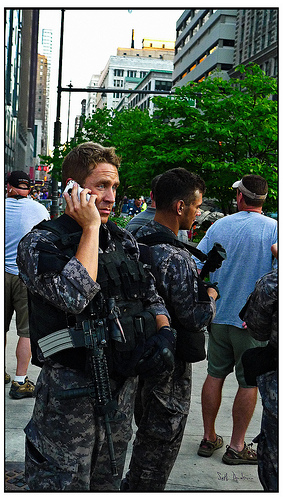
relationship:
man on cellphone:
[33, 140, 160, 493] [61, 180, 94, 210]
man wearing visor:
[188, 169, 279, 465] [218, 176, 267, 203]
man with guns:
[15, 140, 160, 493] [36, 254, 127, 471]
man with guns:
[15, 140, 160, 493] [189, 238, 231, 301]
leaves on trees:
[70, 66, 274, 201] [56, 83, 272, 221]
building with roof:
[122, 75, 171, 131] [123, 69, 171, 79]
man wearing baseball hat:
[3, 169, 54, 400] [5, 168, 30, 193]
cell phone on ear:
[59, 178, 95, 209] [62, 175, 71, 184]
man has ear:
[15, 140, 160, 493] [62, 175, 71, 184]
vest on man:
[19, 216, 157, 378] [15, 140, 160, 493]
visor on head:
[231, 178, 268, 199] [232, 171, 270, 213]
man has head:
[188, 169, 279, 465] [232, 171, 270, 213]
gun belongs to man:
[34, 286, 128, 476] [15, 140, 160, 493]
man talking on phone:
[15, 140, 160, 493] [60, 176, 95, 209]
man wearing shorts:
[188, 169, 279, 465] [203, 312, 272, 389]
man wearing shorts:
[3, 169, 54, 400] [4, 269, 34, 339]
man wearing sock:
[3, 169, 54, 400] [12, 373, 30, 383]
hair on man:
[60, 139, 121, 182] [15, 140, 160, 493]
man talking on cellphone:
[15, 140, 160, 493] [62, 181, 92, 211]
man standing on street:
[15, 140, 160, 493] [6, 307, 267, 490]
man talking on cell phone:
[15, 140, 160, 493] [59, 178, 95, 209]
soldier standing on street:
[121, 166, 217, 491] [6, 307, 267, 490]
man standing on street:
[188, 169, 279, 465] [6, 307, 267, 490]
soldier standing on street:
[235, 241, 279, 491] [6, 307, 267, 490]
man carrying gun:
[15, 140, 160, 493] [129, 311, 155, 372]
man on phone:
[15, 140, 160, 493] [61, 179, 96, 204]